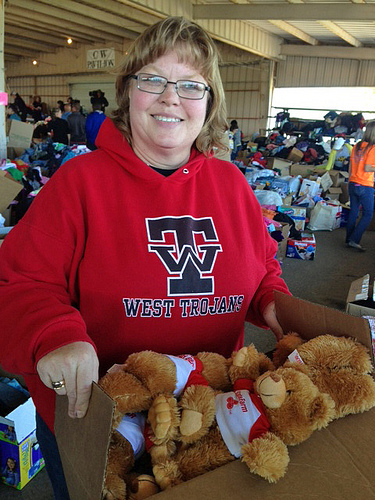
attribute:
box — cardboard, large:
[52, 287, 374, 499]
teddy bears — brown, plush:
[105, 330, 374, 498]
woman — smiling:
[0, 17, 290, 499]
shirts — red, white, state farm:
[116, 352, 271, 460]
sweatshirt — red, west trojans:
[0, 114, 292, 436]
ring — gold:
[49, 380, 66, 390]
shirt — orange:
[347, 140, 374, 185]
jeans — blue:
[346, 180, 374, 243]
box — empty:
[344, 272, 374, 345]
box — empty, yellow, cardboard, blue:
[0, 382, 43, 492]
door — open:
[276, 56, 374, 88]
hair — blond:
[111, 14, 234, 157]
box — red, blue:
[287, 234, 317, 261]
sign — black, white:
[84, 46, 114, 69]